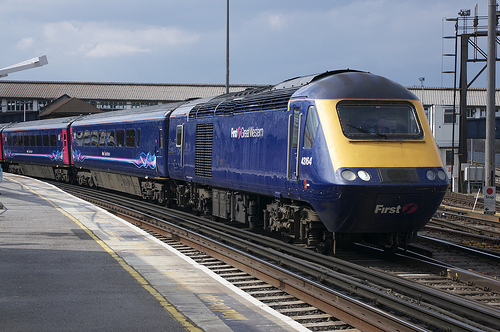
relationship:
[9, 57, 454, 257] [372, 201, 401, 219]
train says first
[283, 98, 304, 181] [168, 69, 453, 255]
door on train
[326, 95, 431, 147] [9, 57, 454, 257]
window on train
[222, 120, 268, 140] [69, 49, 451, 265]
lettering on train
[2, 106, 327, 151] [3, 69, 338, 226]
windows on cars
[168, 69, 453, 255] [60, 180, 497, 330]
train on track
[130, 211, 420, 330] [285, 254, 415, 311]
rust on tracks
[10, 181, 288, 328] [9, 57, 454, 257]
platform to train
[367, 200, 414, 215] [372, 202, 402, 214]
text says first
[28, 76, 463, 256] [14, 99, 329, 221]
train has side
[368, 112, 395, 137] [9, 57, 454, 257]
conductor of train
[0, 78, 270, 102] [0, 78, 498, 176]
roof of building